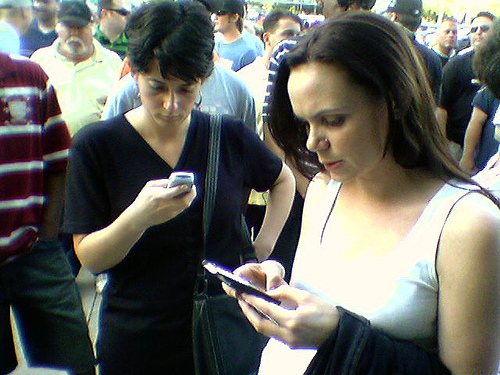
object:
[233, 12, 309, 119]
man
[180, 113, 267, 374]
bag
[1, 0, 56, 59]
man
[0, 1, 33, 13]
cap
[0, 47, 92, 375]
man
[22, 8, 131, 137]
man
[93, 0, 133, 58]
man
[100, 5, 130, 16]
sunglasses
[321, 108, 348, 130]
eye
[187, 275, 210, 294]
metal ring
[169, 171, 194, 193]
phone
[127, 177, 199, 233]
hand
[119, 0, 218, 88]
hair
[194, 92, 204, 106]
earring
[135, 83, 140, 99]
earring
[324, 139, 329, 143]
mole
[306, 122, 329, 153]
nose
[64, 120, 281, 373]
fabric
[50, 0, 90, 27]
cap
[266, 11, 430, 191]
head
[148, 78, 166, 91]
eye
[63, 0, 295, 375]
person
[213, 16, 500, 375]
person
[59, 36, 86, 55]
facial hair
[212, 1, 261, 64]
man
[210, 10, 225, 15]
sunglasses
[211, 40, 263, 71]
blue shirt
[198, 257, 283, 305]
phone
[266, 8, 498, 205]
hair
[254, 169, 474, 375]
tank top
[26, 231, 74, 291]
pocket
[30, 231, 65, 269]
hand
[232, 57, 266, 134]
shirt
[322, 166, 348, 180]
chin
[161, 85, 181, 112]
nose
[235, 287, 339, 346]
hand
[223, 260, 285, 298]
hand